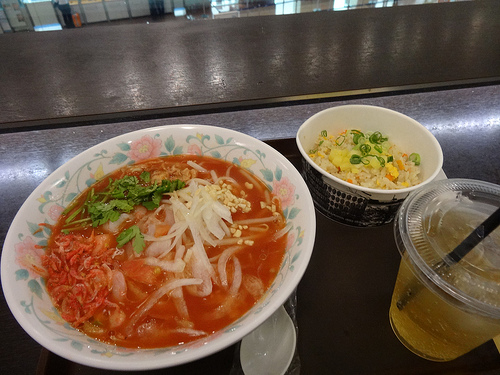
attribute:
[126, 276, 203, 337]
onion — sliced, white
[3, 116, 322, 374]
dish — floral, ceramic, white, large, printed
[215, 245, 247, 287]
onion — sliced, white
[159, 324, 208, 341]
onion — sliced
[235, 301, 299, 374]
spoon — wrapped, plastic, white, packaged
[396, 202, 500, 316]
straw — black, plastic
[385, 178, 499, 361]
cup — plastic, clear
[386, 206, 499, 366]
juice — gold colored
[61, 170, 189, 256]
coriander — leafy, green, garnish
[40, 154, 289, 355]
soup — red, orange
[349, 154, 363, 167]
pepper — green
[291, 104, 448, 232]
bowl — small, cardboard, paper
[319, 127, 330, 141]
pepper — green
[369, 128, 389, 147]
pepper — green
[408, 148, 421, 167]
pepper — green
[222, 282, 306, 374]
wrapper — plastic, clear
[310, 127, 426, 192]
rice — white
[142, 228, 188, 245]
onion — sliced, white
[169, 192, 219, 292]
onion — sliced, white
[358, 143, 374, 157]
scallion — green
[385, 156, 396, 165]
scallion — green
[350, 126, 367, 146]
scallion — green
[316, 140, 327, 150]
scallion — green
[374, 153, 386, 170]
scallion — green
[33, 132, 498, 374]
tray — brown, plastic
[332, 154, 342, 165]
corn — yellow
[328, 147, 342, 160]
corn — yellow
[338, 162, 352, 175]
corn — yellow